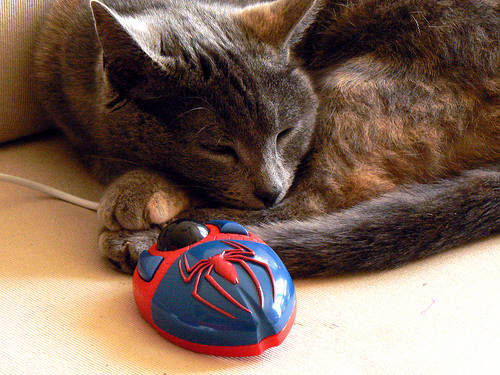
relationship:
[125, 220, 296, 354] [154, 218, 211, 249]
mouse has ball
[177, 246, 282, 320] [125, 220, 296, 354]
spider on mouse